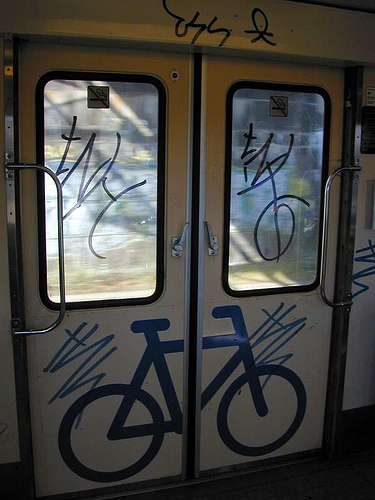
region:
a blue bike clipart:
[54, 273, 321, 471]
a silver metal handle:
[20, 160, 111, 353]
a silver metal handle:
[303, 150, 361, 317]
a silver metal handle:
[1, 157, 72, 380]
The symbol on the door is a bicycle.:
[57, 304, 312, 490]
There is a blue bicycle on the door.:
[51, 305, 308, 487]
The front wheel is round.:
[217, 366, 307, 456]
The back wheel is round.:
[59, 382, 167, 483]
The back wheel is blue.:
[57, 382, 164, 484]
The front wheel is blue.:
[216, 365, 305, 456]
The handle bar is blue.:
[211, 302, 244, 323]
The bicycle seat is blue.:
[129, 314, 171, 334]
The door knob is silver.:
[170, 222, 187, 258]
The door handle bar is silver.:
[4, 158, 71, 338]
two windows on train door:
[43, 73, 336, 298]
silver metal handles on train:
[4, 162, 65, 333]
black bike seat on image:
[130, 313, 169, 337]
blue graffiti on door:
[47, 318, 111, 404]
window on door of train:
[36, 71, 162, 323]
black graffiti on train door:
[30, 98, 143, 261]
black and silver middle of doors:
[178, 53, 211, 490]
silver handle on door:
[320, 163, 359, 306]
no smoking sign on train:
[263, 92, 295, 121]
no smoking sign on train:
[86, 80, 112, 111]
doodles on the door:
[40, 102, 167, 414]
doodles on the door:
[210, 107, 323, 405]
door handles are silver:
[156, 220, 261, 281]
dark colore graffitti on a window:
[52, 113, 151, 261]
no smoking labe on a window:
[85, 83, 111, 109]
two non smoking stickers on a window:
[84, 81, 291, 118]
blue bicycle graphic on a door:
[56, 300, 311, 481]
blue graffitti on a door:
[39, 321, 120, 430]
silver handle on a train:
[4, 160, 64, 336]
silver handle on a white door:
[168, 219, 194, 260]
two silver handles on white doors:
[169, 218, 224, 259]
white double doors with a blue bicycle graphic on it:
[13, 32, 348, 499]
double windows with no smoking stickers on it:
[31, 67, 328, 313]